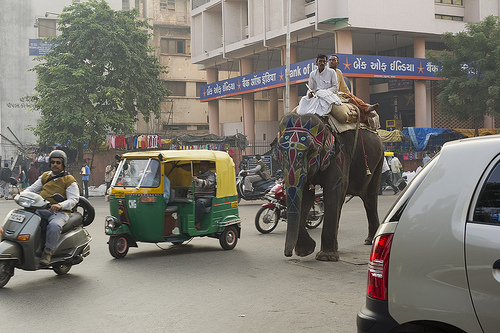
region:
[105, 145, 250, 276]
the taxi is yellow and green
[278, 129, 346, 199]
the elephant is colored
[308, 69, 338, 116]
the shirt is white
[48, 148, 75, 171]
the helmet is grey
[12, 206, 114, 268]
the bike is silver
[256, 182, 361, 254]
the bike is red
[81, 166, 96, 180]
the shirt is blue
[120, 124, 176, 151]
the clothes are being hanged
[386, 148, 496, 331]
the car is silver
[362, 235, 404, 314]
the taillights are red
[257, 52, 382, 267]
two people riding on an elephant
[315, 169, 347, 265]
the front leg of an elephant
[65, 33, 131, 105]
the leaves of a tree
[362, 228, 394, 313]
the taillight of a car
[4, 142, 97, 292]
a man riding a scooter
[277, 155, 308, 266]
the trunk of an elephant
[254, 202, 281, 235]
the wheel of a motorcycle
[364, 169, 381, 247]
the hind leg of an elephant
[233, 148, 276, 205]
a man riding on a scooter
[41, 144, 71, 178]
a man wearing a motorcycle helmet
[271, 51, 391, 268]
Elephant with painted head carrying two riders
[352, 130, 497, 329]
Pale car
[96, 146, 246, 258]
Tiny green and yellow vehicle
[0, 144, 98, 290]
A large man on a motorcycle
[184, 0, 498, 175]
Tall pale building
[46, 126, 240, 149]
Colorful clothing hung up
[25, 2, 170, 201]
A green tree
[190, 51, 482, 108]
Blue sign wrapping around the front of a building with white writing in non-English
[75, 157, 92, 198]
A man in a blue shirt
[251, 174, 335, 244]
Red motorcycle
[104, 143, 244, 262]
yellow and green small three wheel car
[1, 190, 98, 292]
gray colored gas powered street legal scooter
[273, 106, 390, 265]
elephant with fancy headdress on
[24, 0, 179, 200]
large tree in town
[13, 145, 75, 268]
man on scooter dressed in tan vest and white shirt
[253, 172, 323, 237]
red motorcycle located behind elephant on road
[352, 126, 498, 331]
back end of silver suv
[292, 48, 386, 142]
two men riding on elephant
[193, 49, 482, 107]
blue sign on building with white foreign writing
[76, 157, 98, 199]
man dressed in blue shirt standing along street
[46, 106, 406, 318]
a car on the street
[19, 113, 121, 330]
a motorcycle on the street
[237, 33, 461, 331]
an elephant on the raod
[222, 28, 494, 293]
an elephant on the street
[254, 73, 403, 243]
an elephant walking on the road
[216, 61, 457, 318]
an elephant walking on the street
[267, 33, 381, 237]
an elephant carrying people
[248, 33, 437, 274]
an elephant carrying two people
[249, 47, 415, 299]
people on an elephant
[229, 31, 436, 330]
two people on an elephant